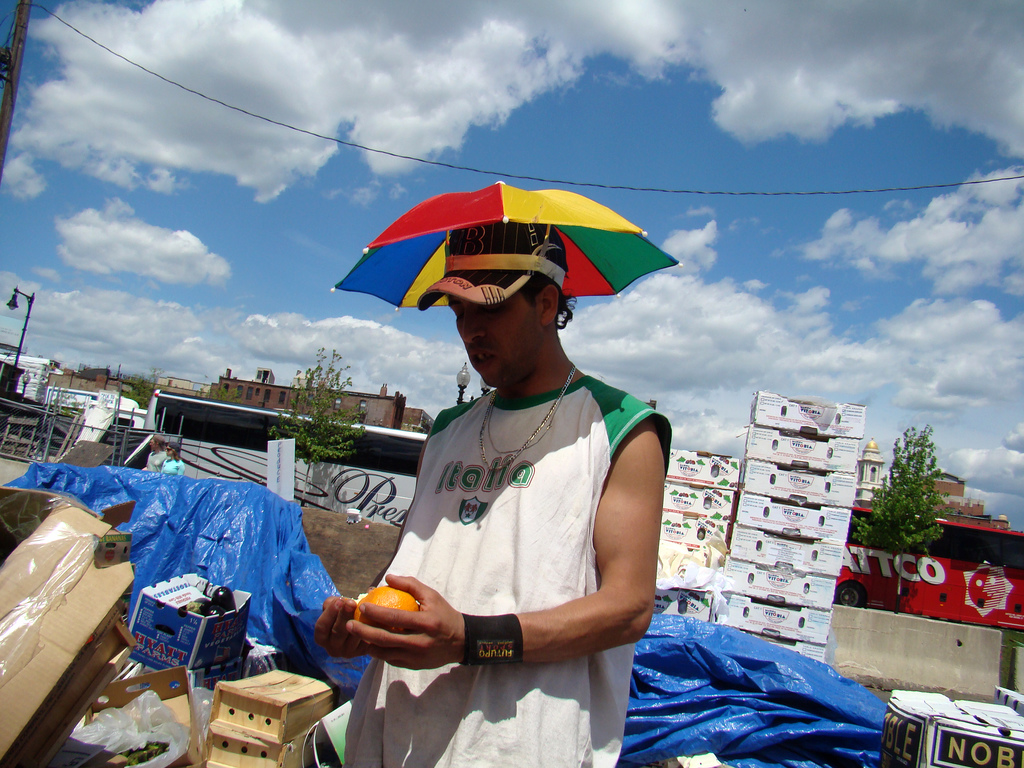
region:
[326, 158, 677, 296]
small umbrella worn by man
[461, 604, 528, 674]
black wristband worn by man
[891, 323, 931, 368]
white clouds in blue sky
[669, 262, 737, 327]
white clouds in blue sky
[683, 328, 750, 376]
white clouds in blue sky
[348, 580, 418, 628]
The orange in the man's left hand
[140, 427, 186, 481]
Two people seen walking behind the left tarp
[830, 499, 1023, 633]
The red bus behind the concrete barriers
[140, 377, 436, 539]
The white bus behind the two people walking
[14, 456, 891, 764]
The blue tarps behind the man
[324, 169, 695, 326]
The man's umbrella hat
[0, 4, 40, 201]
The pole with the wire hanging from it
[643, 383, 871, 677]
The pile of white boxes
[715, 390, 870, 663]
tall stack of supplies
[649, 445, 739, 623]
tall stack of supplies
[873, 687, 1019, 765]
black signing with gold letters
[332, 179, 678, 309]
small colored wearable umbrella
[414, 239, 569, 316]
visor being worn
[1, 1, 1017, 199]
utility wire streaming across the sky from a pole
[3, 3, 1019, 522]
large white clouds in a bright blue sky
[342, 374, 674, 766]
white shirt with green shoulders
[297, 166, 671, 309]
man wearing colorful umbrella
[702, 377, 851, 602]
stacked white boxes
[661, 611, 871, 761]
blue tarp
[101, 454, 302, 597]
blue tarp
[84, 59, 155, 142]
white clouds in blue sky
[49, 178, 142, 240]
white clouds in blue sky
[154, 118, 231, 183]
white clouds in blue sky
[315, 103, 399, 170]
white clouds in blue sky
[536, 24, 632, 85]
white clouds in blue sky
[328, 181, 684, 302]
the umbrella hat on the man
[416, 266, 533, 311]
the bill of the mans hat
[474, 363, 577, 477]
the necklace around the neck of the man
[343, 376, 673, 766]
the white tank top on the man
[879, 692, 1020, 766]
the white box behind the man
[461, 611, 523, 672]
the black band on the man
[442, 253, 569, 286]
the strap for the hat is white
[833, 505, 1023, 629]
the red bus behind the man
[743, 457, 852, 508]
A closed cardboard box.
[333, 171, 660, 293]
umbrella hat on head of man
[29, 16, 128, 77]
white clouds in blue sky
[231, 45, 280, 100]
white clouds in blue sky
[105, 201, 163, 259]
white clouds in blue sky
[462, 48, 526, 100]
white clouds in blue sky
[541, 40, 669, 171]
white clouds in blue sky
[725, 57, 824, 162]
white clouds in blue sky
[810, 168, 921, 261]
white clouds in blue sky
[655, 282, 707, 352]
white clouds in blue sky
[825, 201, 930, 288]
white clouds in blue sky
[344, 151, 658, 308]
umbrella hat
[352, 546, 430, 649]
orange held by man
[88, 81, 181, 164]
white clouds in blue sky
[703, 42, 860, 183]
white clouds in blue sky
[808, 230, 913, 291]
white clouds in blue sky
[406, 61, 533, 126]
white clouds in blue sky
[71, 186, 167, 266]
white clouds in blue sky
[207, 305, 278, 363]
white clouds in blue sky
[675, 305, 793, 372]
white clouds in blue sky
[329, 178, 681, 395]
man wearing an umbrella hat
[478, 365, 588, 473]
man is wearing necklaces